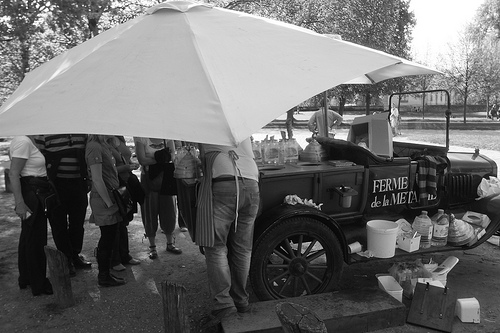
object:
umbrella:
[0, 0, 445, 148]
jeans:
[204, 176, 261, 311]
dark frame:
[389, 89, 451, 149]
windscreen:
[390, 91, 448, 148]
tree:
[0, 0, 68, 100]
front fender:
[253, 204, 351, 263]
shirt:
[202, 137, 259, 183]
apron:
[195, 150, 255, 248]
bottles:
[284, 138, 298, 164]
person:
[195, 137, 261, 330]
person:
[8, 135, 57, 296]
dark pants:
[47, 180, 88, 258]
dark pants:
[18, 175, 51, 294]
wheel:
[249, 217, 345, 301]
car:
[175, 89, 500, 301]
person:
[85, 134, 128, 288]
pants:
[96, 224, 119, 272]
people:
[34, 134, 92, 277]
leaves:
[46, 15, 57, 29]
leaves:
[24, 25, 39, 34]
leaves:
[0, 24, 6, 34]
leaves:
[43, 46, 50, 56]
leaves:
[110, 8, 122, 20]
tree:
[46, 0, 135, 61]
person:
[135, 137, 183, 259]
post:
[161, 280, 190, 333]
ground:
[1, 127, 498, 331]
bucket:
[366, 219, 400, 258]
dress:
[85, 141, 124, 226]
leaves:
[8, 34, 40, 57]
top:
[145, 0, 198, 15]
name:
[370, 176, 437, 208]